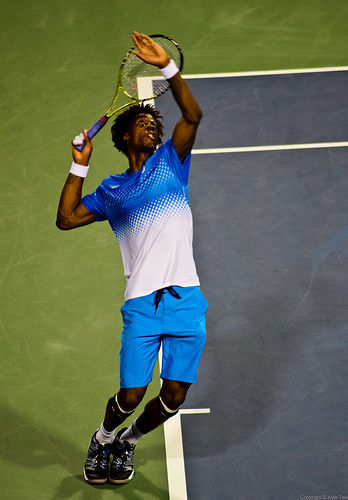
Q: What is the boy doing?
A: Reaching.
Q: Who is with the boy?
A: No one.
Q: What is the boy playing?
A: Tennis.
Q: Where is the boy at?
A: Tennis court.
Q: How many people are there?
A: One.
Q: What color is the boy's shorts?
A: Blue.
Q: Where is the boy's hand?
A: Racket net.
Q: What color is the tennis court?
A: Gray.